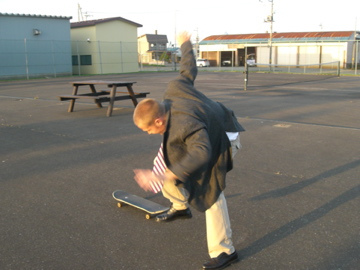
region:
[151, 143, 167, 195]
red and white neck tie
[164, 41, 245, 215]
a grey suit coat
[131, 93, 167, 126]
a blond brush cut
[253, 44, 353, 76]
four closed white garage doors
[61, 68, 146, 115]
a wooden picnic table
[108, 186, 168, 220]
skateboard with yellow wheels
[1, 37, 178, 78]
tall chain link fence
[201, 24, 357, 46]
red stripe across metal roof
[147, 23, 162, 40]
a chimeny on a black roof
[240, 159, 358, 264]
shadow of man's legs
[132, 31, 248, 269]
young boy stomping ground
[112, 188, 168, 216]
black skateboard on ground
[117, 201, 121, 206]
yellow wheel on skateboard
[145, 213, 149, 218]
yellow wheel on skateboard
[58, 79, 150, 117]
empty wooden picnic bench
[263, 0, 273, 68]
tall wooden utility pole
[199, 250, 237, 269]
Shiny black dress shoe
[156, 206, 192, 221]
shiny black dress shoe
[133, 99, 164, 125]
short blonde colored hair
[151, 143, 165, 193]
red and white striped tie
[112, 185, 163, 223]
a skateboard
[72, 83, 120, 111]
a table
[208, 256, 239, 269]
black shoes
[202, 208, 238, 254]
the person is wearing white pants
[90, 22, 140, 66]
a white building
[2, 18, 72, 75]
a blue building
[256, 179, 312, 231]
a shadow on the ground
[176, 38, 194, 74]
the mans arm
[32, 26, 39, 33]
a light on the building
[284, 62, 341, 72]
a fence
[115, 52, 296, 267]
man is falling off skateboard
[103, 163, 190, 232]
the skateboard is black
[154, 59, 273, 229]
man's jacket is gray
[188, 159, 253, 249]
man's pants are khaki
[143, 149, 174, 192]
man is wearing a tie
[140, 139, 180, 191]
the tie is striped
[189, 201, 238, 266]
man's shoe is black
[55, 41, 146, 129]
bench in the background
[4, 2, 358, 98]
buildings in the background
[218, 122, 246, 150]
man's shirt is white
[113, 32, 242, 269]
a young man falling off skateboard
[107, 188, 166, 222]
a grey skateboard on ground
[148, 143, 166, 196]
a red and white striped tie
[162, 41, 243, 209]
a men's grey suit jacket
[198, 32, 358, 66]
white building in distance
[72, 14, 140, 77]
yellow building in distance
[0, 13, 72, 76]
blue building in distance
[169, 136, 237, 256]
a pair of men's tan pants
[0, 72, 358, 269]
a paved courtyard